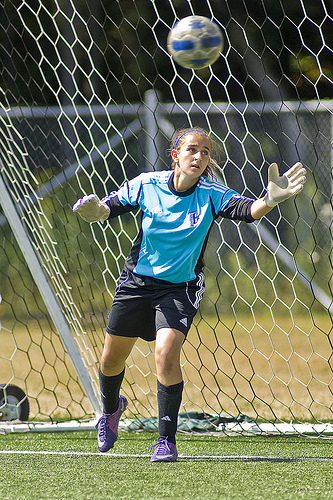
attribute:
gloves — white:
[262, 163, 311, 203]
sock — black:
[149, 379, 189, 432]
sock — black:
[94, 371, 127, 409]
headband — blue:
[173, 123, 209, 146]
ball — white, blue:
[157, 8, 230, 81]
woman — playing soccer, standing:
[61, 122, 309, 462]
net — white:
[11, 11, 330, 421]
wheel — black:
[3, 384, 28, 419]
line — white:
[17, 442, 323, 465]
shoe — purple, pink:
[150, 443, 176, 464]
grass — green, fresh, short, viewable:
[30, 437, 300, 499]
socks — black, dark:
[95, 369, 189, 415]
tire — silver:
[3, 382, 19, 422]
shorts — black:
[109, 275, 198, 343]